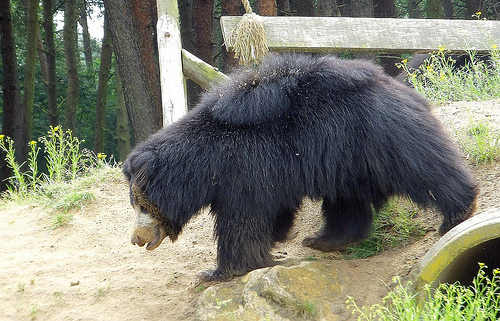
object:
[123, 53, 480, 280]
bear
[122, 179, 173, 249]
face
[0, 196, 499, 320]
sand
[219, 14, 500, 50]
board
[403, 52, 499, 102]
weeds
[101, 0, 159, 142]
trunks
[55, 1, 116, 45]
sky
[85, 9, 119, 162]
trees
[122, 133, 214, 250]
head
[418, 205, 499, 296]
tunnel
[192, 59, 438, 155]
back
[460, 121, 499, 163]
shrubs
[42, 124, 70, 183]
plants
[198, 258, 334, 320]
rocks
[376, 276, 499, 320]
plants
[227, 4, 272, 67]
rope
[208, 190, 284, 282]
legs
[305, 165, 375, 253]
legs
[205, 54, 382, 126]
fur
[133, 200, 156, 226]
patch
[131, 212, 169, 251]
snout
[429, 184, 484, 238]
foot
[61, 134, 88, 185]
stems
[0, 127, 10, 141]
flowers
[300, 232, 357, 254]
paw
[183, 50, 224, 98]
plank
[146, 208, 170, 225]
dirt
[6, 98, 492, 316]
path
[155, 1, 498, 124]
fence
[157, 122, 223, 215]
neck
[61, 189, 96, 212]
patch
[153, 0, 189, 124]
plank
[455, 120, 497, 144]
grass